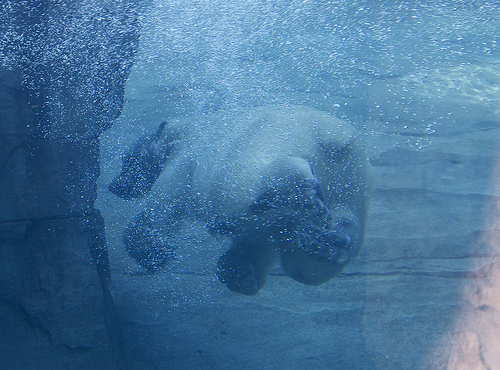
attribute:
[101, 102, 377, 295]
polar bear — white, swimming, large, big, bright, light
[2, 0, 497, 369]
water — bright, deep, active, clear, vibrant, clean, blue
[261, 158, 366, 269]
legs — white, light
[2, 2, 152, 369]
rock — gray, grey, big, wide, dark, tall, large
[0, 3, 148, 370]
wall — rock